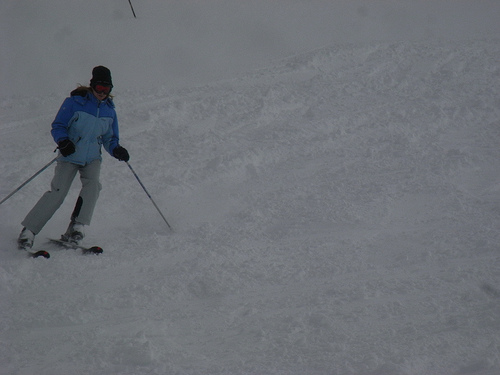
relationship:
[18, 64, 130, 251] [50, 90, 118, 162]
woman on coat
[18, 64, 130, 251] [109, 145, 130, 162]
woman on glove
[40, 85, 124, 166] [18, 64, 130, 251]
jacket on a woman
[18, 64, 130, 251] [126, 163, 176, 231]
woman carrying poles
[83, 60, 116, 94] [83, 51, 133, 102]
hat on head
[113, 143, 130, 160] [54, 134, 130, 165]
glove on hand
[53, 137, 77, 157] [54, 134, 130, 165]
glove on hand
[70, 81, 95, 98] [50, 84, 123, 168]
hood on jacket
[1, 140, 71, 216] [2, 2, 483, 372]
pole in photo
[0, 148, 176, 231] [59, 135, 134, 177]
poles in hands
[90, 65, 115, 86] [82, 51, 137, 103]
hat on head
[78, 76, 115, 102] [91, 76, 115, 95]
goggles on face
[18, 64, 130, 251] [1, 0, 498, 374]
woman skiing snow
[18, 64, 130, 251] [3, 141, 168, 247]
woman wearing gear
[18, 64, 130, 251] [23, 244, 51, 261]
woman on ski equipment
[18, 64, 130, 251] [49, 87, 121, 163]
woman wearing jacket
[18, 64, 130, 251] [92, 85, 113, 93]
woman wearing goggles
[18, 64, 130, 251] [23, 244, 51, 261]
woman using ski equipment